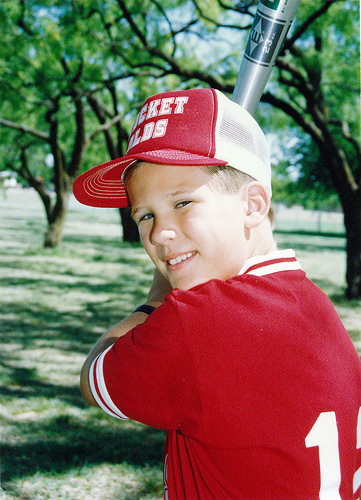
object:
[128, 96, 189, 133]
word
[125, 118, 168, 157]
word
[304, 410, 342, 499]
number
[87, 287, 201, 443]
sleeve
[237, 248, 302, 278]
collar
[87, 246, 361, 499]
shirt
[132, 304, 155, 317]
band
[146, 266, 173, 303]
hand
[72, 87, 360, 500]
boy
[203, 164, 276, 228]
hair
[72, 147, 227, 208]
bill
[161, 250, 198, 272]
smile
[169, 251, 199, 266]
teeth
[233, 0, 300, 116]
bat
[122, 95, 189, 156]
writing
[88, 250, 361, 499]
jersey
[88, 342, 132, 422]
trim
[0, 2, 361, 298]
trees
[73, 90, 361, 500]
player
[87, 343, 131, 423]
stripe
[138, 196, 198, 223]
eyes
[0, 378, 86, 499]
grass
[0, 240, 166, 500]
ground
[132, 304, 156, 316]
tape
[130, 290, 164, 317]
wrist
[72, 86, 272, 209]
ball cap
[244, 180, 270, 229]
ear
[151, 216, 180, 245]
nose